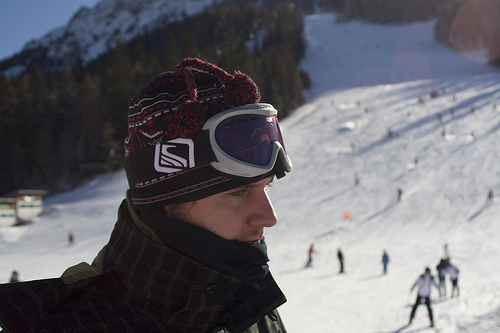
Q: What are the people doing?
A: Skiing.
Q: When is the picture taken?
A: Daytime.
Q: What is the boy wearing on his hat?
A: Goggles.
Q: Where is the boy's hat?
A: On his head.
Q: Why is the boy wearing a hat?
A: It is cold outside.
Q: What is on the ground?
A: Snow.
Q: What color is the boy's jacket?
A: Black.